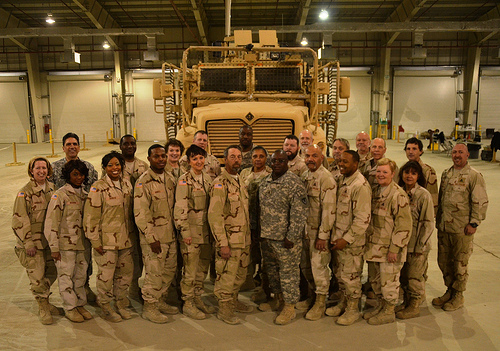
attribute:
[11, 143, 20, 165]
pole — yellow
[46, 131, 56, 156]
pole — yellow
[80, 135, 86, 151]
pole — yellow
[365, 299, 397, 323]
boots — brown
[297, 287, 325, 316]
boots — brown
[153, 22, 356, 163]
truck — yellow, tan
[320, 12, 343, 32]
light — white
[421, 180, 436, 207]
ground — parked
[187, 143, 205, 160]
hair — black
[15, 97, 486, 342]
soldiers — standing together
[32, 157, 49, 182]
face — smiling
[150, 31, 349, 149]
vehicle — military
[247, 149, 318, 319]
soldier — camoflauge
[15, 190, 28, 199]
patches — american flag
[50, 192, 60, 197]
patches — american flag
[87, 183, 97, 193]
patches — american flag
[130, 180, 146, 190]
patches — american flag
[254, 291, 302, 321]
boots — brown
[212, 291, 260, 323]
boots — brown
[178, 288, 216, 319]
boots — brown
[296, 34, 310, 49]
light — white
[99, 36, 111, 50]
light — white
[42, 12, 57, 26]
light — white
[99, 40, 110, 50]
lights — on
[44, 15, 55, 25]
lights — on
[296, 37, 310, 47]
lights — on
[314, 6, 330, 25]
lights — on